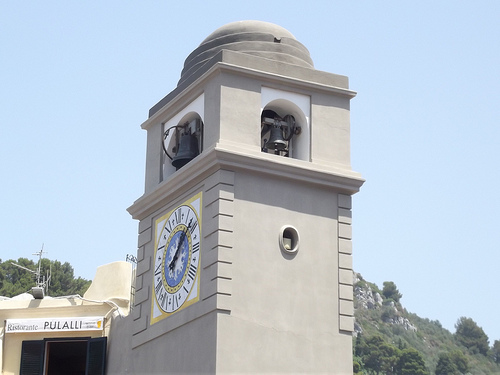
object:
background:
[0, 245, 500, 375]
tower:
[106, 20, 365, 375]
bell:
[264, 125, 290, 151]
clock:
[153, 206, 201, 313]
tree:
[381, 281, 402, 303]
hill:
[354, 268, 500, 375]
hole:
[279, 225, 300, 254]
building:
[0, 262, 131, 375]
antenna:
[32, 244, 54, 293]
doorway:
[40, 337, 89, 374]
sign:
[5, 319, 102, 331]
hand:
[173, 219, 194, 261]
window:
[15, 340, 44, 375]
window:
[87, 338, 109, 375]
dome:
[198, 17, 298, 47]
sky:
[0, 0, 500, 261]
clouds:
[91, 132, 135, 146]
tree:
[59, 262, 74, 290]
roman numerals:
[192, 242, 200, 254]